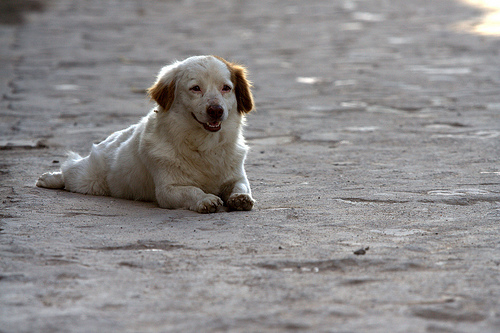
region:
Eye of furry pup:
[219, 83, 237, 96]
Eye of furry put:
[186, 80, 207, 93]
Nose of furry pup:
[206, 100, 223, 122]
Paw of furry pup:
[229, 190, 257, 213]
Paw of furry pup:
[186, 192, 223, 211]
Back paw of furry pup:
[33, 166, 68, 189]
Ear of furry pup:
[148, 68, 178, 107]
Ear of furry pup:
[235, 65, 257, 117]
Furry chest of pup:
[168, 137, 243, 177]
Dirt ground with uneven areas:
[290, 182, 430, 254]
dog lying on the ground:
[27, 55, 274, 217]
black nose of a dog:
[200, 99, 227, 121]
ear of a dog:
[142, 60, 182, 115]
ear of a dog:
[224, 63, 258, 118]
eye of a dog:
[187, 79, 207, 98]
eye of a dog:
[217, 79, 235, 94]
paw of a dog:
[224, 185, 259, 213]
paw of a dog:
[190, 194, 228, 214]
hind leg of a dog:
[28, 162, 65, 189]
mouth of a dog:
[202, 113, 225, 133]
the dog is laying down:
[33, 26, 299, 280]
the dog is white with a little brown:
[17, 58, 269, 223]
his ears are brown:
[143, 52, 277, 126]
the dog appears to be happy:
[141, 46, 286, 248]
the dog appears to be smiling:
[150, 30, 270, 223]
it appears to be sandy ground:
[314, 38, 479, 308]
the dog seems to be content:
[34, 35, 296, 223]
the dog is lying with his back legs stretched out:
[31, 51, 279, 230]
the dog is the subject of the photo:
[1, 0, 499, 321]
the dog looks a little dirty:
[47, 40, 278, 241]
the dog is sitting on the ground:
[14, 25, 285, 250]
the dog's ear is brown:
[228, 44, 255, 132]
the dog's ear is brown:
[141, 68, 187, 124]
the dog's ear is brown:
[221, 46, 278, 145]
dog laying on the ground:
[23, 42, 323, 273]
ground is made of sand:
[287, 152, 436, 284]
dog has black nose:
[199, 98, 226, 128]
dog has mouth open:
[182, 100, 231, 131]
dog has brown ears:
[137, 40, 187, 110]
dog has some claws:
[181, 170, 263, 224]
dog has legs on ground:
[31, 56, 305, 274]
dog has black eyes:
[188, 72, 205, 94]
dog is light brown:
[39, 6, 277, 327]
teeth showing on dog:
[199, 110, 238, 150]